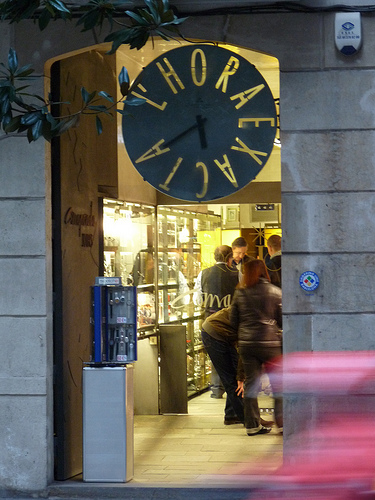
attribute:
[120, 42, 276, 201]
clock — gold, black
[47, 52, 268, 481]
window — glass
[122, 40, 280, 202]
sign — round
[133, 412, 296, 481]
ground — brown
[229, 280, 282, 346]
jacket — leather 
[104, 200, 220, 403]
display case — glass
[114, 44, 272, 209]
sign — yellow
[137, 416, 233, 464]
floor — wood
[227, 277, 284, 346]
jacket — leather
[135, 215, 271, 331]
doors — glass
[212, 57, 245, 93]
r — letter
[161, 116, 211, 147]
hand — hour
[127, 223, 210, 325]
items — for sale